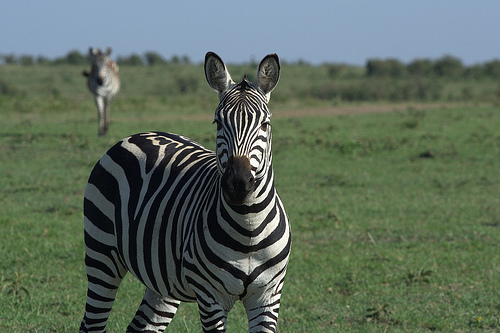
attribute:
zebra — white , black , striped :
[83, 46, 119, 136]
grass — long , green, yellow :
[307, 112, 494, 330]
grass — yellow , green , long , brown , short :
[0, 64, 498, 331]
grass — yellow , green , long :
[304, 110, 467, 222]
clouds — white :
[215, 18, 280, 41]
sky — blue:
[2, 1, 499, 56]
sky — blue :
[1, 3, 487, 60]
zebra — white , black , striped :
[76, 44, 302, 331]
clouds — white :
[213, 24, 285, 41]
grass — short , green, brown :
[411, 186, 485, 248]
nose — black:
[218, 157, 270, 211]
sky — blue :
[281, 12, 363, 50]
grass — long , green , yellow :
[315, 201, 477, 306]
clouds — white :
[6, 4, 495, 65]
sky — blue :
[1, 0, 499, 65]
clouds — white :
[139, 6, 182, 51]